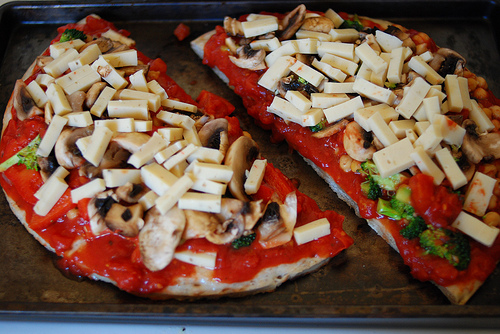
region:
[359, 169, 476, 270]
Pieces of broccoli on a pizza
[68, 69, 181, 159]
Chunks of cheese on a pizza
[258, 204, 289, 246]
Piece of mushroom on a pizza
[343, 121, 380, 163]
Mushroom piece on pizza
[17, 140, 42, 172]
Tiny piece of green broccoli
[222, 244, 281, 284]
Red sauce on pizza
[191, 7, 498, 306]
Half a pizza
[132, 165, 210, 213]
White chunks of cheese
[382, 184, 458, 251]
Pieces of broccoli on pizza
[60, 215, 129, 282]
Sauce of a pizza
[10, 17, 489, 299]
uncooked pizza with chunks of cheese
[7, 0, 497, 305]
round pizza cut in half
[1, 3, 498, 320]
pizza cut in half with tomato sauce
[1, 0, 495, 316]
pizza cut in half with mushrooms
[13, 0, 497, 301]
pizza cut in half with broccoli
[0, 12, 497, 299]
pizza sauce is red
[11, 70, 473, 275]
broccoli is fresh and green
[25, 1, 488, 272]
mushrooms are brown and fresh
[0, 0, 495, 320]
pizza is sitting on metal pan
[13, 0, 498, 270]
cheese is cut in rectangles and white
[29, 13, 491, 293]
two halves of raw pizza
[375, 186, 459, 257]
broccoli on tomato sauce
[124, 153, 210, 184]
wedges of cheese on pizza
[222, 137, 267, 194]
mushroom on edge of pizza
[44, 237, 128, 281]
tomato sauce dripping off pizza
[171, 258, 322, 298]
crust of raw pizza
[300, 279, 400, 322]
brown cookie sheet under pizza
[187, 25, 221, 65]
raw dough on corner of pizza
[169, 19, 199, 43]
chunk of tomato on cookie sheet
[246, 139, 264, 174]
black part of sliced mushroom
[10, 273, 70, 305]
Pan the pizza is in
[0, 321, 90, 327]
Blue surface the pan rests on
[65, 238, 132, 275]
Tomato sauce on the pizza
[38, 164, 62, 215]
Hunks of mozzarella cheese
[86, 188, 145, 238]
Mushroom on the pizza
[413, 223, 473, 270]
Broccoli on the pizza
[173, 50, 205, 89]
Empty space between the two halves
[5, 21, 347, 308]
Entire left half of the pizza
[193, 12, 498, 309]
Entire right half of the pizza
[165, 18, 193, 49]
Stray hunk of tomato on the pan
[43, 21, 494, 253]
pizza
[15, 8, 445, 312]
pizza cut in half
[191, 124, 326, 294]
mushrooms on a pizza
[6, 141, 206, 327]
tomato sauce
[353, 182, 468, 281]
broccoli on pizza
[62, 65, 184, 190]
chunks of cheese on pizza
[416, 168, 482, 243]
slices of tomato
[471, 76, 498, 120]
garbanzo beans on pizza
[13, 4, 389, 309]
baking pan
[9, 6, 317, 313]
brown colored baking pan